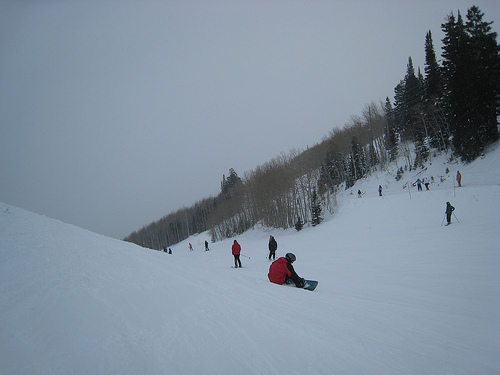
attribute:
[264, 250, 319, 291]
snowboarder — fallen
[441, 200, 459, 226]
skier — black, blue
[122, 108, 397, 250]
trees — dead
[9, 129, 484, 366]
snow — white, hilly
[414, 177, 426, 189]
jacket — blue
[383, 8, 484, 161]
forest — filled 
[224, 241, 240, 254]
jacket — red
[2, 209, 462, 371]
snow — covered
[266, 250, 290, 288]
snowboarder jacket — red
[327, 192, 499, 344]
snow covered slope — crowded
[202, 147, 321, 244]
bunch of  trees — leafless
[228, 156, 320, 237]
trees are bare — tall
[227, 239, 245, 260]
person's jacket — red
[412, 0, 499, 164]
trees are green — tall